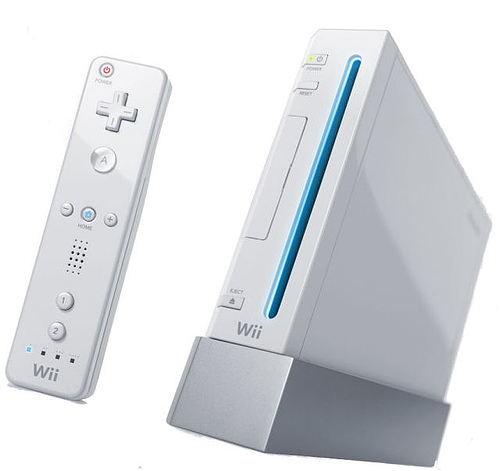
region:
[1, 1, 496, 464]
A WII CONSOLE AND REMOTE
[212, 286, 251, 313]
THE EJECT BUTTON ON THE WII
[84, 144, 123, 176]
THE A BUTTON ON THE WII REMOTE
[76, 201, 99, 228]
THE HOME BUTTON ON THE REMOTE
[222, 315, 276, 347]
THE WII LOGO ON THE CONSOLE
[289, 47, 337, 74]
THE POWER BUTTON ON THE CONSOLE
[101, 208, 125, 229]
THE PLUS BUTTON ON THE REMOTE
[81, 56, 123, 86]
THE RED POWER BUTTON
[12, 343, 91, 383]
THE CHARGE INDICATOR LIGHTS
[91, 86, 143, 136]
THE DIRECTION BUTTONS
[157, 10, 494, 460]
Wii console is white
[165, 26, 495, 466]
Wii console has blue slot for game cartridge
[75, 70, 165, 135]
buttons allow player to move left, right, up, or down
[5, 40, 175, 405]
Wii remote is white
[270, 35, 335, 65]
power button for Wii console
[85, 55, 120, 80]
red and white power button for Wii remote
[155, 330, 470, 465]
silver base for Wii console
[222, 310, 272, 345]
Wii logo at bottom of console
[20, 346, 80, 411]
Wii logo at bottom of remote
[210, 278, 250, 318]
button to eject cartridge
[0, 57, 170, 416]
a WII game controller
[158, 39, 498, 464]
a white nintendo wii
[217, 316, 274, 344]
company logo on front of console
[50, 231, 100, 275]
speaker on game controller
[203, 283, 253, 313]
eject button on game console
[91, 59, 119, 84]
power button on game controller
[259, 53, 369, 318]
blue cd slot on game console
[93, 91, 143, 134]
directional buttons on game controller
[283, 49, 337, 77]
power button on game console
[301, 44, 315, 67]
green power light on game console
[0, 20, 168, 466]
Wii remote controller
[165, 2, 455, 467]
White Wii game console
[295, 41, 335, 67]
Power button on Wii Console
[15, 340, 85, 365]
Player number indicator lights on remote control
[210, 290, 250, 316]
Eject button on Wii console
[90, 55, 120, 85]
Power button on Wii remote control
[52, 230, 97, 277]
Speaker on Wii remote control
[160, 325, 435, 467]
Base for Wii console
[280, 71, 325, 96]
Reset button on Will console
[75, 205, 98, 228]
Home button on Wii remote control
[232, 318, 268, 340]
gray writing on the console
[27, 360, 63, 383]
gray writing on the controller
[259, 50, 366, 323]
a blue disc tray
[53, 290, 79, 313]
a round button on the controller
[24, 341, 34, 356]
a blue light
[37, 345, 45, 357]
a dark light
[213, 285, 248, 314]
a rectangular eject button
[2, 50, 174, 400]
a rectangular game controller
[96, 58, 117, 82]
a round power button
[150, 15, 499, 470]
a white and gray game controller